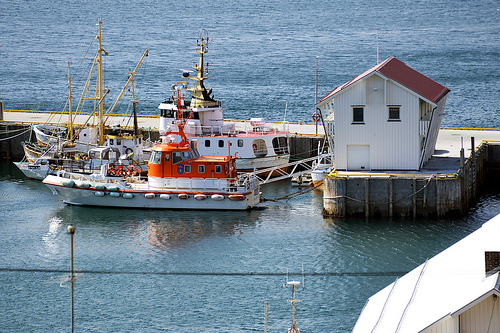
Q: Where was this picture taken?
A: Harbor.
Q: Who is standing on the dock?
A: No one.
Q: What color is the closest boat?
A: Orange and white.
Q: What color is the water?
A: Blue.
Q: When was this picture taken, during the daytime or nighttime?
A: Daytime.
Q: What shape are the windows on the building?
A: Square.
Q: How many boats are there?
A: Two.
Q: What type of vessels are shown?
A: Boats.